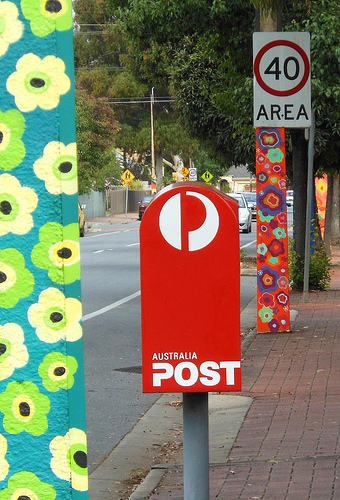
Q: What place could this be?
A: It is a sidewalk.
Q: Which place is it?
A: It is a sidewalk.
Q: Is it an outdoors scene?
A: Yes, it is outdoors.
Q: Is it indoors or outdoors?
A: It is outdoors.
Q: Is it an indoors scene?
A: No, it is outdoors.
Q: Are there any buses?
A: No, there are no buses.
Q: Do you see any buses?
A: No, there are no buses.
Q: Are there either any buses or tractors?
A: No, there are no buses or tractors.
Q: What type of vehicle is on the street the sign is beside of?
A: The vehicle is a car.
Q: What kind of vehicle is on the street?
A: The vehicle is a car.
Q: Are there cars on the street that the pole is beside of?
A: Yes, there is a car on the street.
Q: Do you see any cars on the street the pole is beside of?
A: Yes, there is a car on the street.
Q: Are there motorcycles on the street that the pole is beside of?
A: No, there is a car on the street.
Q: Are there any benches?
A: No, there are no benches.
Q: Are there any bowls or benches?
A: No, there are no benches or bowls.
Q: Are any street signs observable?
A: Yes, there is a street sign.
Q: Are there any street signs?
A: Yes, there is a street sign.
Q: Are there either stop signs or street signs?
A: Yes, there is a street sign.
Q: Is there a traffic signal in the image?
A: No, there are no traffic lights.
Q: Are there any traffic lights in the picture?
A: No, there are no traffic lights.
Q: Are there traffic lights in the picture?
A: No, there are no traffic lights.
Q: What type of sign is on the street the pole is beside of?
A: The sign is a street sign.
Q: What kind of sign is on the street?
A: The sign is a street sign.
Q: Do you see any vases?
A: No, there are no vases.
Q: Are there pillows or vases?
A: No, there are no vases or pillows.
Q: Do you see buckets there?
A: No, there are no buckets.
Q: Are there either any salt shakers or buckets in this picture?
A: No, there are no buckets or salt shakers.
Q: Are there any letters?
A: Yes, there are letters.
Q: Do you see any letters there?
A: Yes, there are letters.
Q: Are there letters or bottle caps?
A: Yes, there are letters.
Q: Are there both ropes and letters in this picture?
A: No, there are letters but no ropes.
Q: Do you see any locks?
A: No, there are no locks.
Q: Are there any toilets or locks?
A: No, there are no locks or toilets.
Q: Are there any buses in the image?
A: No, there are no buses.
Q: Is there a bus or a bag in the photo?
A: No, there are no buses or bags.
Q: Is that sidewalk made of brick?
A: Yes, the sidewalk is made of brick.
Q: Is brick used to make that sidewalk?
A: Yes, the sidewalk is made of brick.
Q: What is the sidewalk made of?
A: The sidewalk is made of brick.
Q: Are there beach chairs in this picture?
A: No, there are no beach chairs.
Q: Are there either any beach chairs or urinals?
A: No, there are no beach chairs or urinals.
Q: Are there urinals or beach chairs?
A: No, there are no beach chairs or urinals.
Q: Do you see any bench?
A: No, there are no benches.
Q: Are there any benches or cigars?
A: No, there are no benches or cigars.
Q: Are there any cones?
A: No, there are no cones.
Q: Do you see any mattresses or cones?
A: No, there are no cones or mattresses.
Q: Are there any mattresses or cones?
A: No, there are no cones or mattresses.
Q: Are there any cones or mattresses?
A: No, there are no cones or mattresses.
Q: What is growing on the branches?
A: The leaves are growing on the branches.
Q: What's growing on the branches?
A: The leaves are growing on the branches.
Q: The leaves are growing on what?
A: The leaves are growing on the branches.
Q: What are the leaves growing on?
A: The leaves are growing on the branches.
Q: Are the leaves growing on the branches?
A: Yes, the leaves are growing on the branches.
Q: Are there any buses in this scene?
A: No, there are no buses.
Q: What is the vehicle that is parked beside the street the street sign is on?
A: The vehicle is a car.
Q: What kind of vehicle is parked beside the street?
A: The vehicle is a car.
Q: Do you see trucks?
A: No, there are no trucks.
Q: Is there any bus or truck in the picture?
A: No, there are no trucks or buses.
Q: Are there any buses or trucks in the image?
A: No, there are no trucks or buses.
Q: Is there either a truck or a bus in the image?
A: No, there are no trucks or buses.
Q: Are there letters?
A: Yes, there are letters.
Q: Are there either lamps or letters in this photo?
A: Yes, there are letters.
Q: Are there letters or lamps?
A: Yes, there are letters.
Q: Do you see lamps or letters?
A: Yes, there are letters.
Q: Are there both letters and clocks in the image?
A: No, there are letters but no clocks.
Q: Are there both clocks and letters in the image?
A: No, there are letters but no clocks.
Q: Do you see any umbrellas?
A: No, there are no umbrellas.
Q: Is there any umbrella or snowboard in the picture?
A: No, there are no umbrellas or snowboards.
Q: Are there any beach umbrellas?
A: No, there are no beach umbrellas.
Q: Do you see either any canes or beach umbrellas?
A: No, there are no beach umbrellas or canes.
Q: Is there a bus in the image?
A: No, there are no buses.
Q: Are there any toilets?
A: No, there are no toilets.